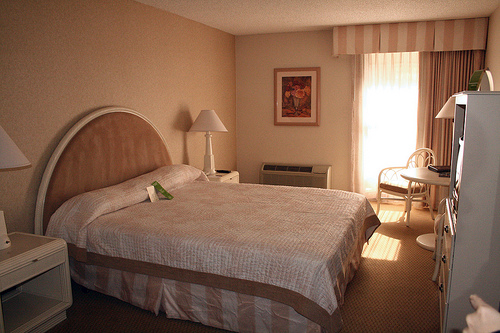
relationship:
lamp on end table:
[169, 93, 242, 193] [203, 169, 240, 183]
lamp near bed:
[188, 109, 228, 177] [32, 107, 382, 331]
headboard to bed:
[34, 107, 172, 236] [32, 107, 382, 331]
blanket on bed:
[42, 163, 384, 331] [32, 107, 382, 331]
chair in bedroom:
[376, 148, 438, 227] [0, 1, 500, 333]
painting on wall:
[273, 67, 321, 126] [235, 32, 358, 190]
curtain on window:
[313, 18, 498, 191] [348, 49, 485, 204]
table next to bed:
[0, 227, 76, 331] [32, 107, 382, 331]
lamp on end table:
[188, 109, 228, 177] [198, 168, 240, 183]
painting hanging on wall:
[273, 67, 321, 126] [233, 19, 358, 192]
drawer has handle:
[439, 195, 456, 269] [442, 223, 449, 233]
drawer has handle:
[438, 233, 448, 329] [438, 252, 445, 262]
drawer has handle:
[435, 261, 447, 331] [438, 282, 444, 292]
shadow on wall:
[169, 102, 195, 163] [0, 2, 234, 232]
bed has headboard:
[32, 107, 382, 331] [39, 85, 184, 195]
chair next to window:
[376, 146, 437, 223] [355, 50, 421, 199]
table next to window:
[400, 169, 450, 228] [355, 50, 421, 199]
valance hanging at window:
[332, 24, 489, 51] [332, 44, 467, 199]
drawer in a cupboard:
[438, 233, 448, 329] [436, 89, 498, 331]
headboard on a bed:
[28, 101, 176, 245] [90, 132, 415, 330]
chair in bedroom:
[376, 148, 438, 227] [2, 2, 497, 297]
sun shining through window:
[356, 80, 421, 264] [355, 50, 421, 199]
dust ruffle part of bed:
[66, 230, 383, 332] [32, 107, 382, 331]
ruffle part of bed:
[266, 60, 331, 133] [32, 107, 382, 331]